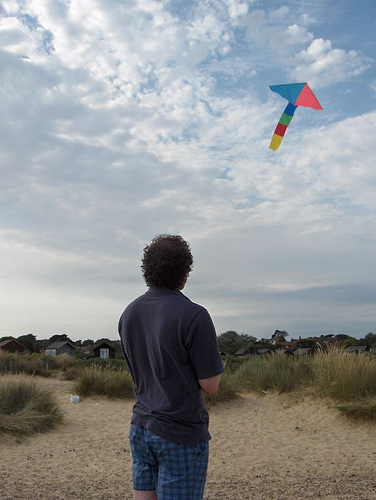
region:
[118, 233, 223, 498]
the man on the sand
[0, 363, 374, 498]
the sand on the ground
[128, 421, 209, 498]
the shorts on the man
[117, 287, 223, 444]
the shirt on the man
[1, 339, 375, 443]
the bushes of tall grass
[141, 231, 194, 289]
the hair on the man's head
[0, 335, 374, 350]
the homes in the distance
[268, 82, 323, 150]
the kite in the sky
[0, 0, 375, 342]
the clouds in the sky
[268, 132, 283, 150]
the yellow part on the kite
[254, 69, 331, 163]
a kite in the air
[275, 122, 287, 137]
red colour on a kite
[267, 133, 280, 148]
yellow colour on a kite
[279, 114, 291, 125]
green colour on a kite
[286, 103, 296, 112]
blue colour on a kite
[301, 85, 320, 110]
pink colour on a kite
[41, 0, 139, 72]
white clouds in the sky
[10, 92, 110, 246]
dark clouds in the sky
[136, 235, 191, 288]
the head of a person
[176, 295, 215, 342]
the shoulder of a person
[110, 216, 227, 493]
A man standing in a sand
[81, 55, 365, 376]
Man is flying a kite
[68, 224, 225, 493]
The man has curly hair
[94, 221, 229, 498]
Man wearing blue color T-shirt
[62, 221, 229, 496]
Man wearing a trouser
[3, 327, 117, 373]
Small huts behind the grass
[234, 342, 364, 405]
Green color tall grass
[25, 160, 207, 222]
The blue color sky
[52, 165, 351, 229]
The sky is cloudy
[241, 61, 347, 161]
Different colors in the kite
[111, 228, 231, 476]
this is a man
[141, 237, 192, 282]
this is the head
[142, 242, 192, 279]
the hair is shaggy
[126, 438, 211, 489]
this is a short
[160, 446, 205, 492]
the short is blue in color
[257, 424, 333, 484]
this is the ground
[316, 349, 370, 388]
these are the grass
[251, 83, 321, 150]
this is a kite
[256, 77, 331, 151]
the kite is colorful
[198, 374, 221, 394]
this is the elbow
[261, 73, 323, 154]
the kite is in the air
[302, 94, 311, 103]
the kite is pink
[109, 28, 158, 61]
the clouds are fluffy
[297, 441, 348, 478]
the sand is tan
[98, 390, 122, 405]
grass is growing through the sand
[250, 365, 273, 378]
the grass is green in color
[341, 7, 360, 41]
the sky is blue in color